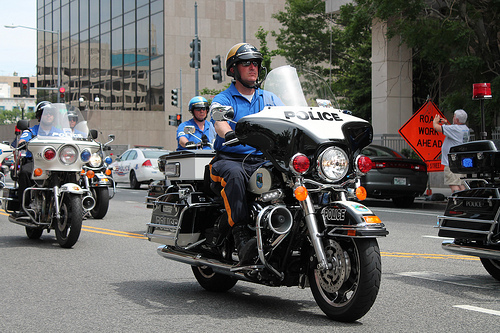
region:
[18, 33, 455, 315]
Police riding on motorcycles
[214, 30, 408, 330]
The policeman is wearing sunglasses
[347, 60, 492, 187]
The man is working on sign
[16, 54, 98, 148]
The traffic lights are red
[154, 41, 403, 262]
policeman has orange stripe on pants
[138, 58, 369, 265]
blue lights on motorcycle by policeman's knee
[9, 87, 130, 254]
motorcycle has a red light and blue light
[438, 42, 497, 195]
red light on back of motorcycle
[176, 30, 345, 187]
police wearing blue shirts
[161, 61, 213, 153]
policeman has blue helmet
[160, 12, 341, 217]
Police officer on a bike.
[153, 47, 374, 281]
Police officer wearing a helmet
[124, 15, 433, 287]
Police officer riding down the road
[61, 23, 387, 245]
Police officers riding the street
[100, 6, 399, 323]
Police officer patrolling the road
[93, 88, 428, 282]
Police officer on a Harley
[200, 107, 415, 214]
Lights on the motorcycle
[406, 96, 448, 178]
Road work sign along the street.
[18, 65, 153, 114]
Traffic lights at an intersection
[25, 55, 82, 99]
Red light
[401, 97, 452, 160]
The diamond shaped road sign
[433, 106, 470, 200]
The man taking a photo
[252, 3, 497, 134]
The trees in the background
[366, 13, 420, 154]
The white pillar in front of the trees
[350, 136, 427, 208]
The car parked in front of the pillar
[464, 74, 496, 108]
The red light near the man taking a photo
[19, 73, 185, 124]
The red lights in the background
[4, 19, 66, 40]
The light hanging over the street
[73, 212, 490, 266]
The yellow line in the street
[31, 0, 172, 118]
The building with walls made of windows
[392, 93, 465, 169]
A orange diamond shaped sign.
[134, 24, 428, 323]
A couple of police on motorcycles.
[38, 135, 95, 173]
A headlight with a red light and a blue light.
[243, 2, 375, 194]
Police written on the motorcycle.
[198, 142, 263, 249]
Blue pants with a orange stripe.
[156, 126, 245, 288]
The storage area for a motorcycle.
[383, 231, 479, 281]
A double yellow line.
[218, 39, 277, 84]
A man wearing a helmet and sunglasses.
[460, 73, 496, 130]
A red police light.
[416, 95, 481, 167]
A man in gray shirt touching the orange sign.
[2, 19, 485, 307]
a police parade through a city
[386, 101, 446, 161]
an orange construction sign on the side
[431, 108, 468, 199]
a man taking a photo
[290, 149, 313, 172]
red caution light on the front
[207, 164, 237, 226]
a yellow stripe on pants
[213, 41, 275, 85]
a helmet on a head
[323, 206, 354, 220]
words on the fender of the motorcycle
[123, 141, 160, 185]
a police car parked on the curb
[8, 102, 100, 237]
a policeman riding a motorcycle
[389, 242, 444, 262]
yellow lines marking the street